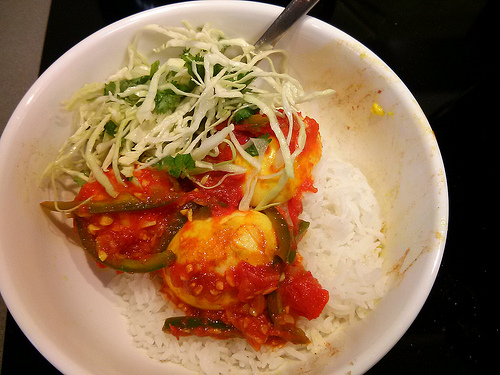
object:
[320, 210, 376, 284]
rice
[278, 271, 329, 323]
tomato sauce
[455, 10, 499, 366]
black mat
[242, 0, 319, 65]
utensil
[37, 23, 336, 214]
garnish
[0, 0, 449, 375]
bowl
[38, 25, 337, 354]
food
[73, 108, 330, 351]
sauce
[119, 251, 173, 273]
pepper